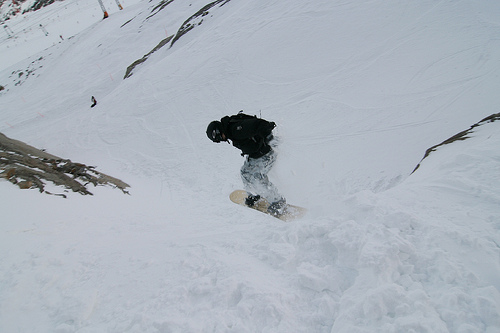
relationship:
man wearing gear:
[205, 109, 289, 218] [239, 120, 271, 159]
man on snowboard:
[205, 109, 289, 218] [228, 189, 305, 224]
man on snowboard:
[205, 109, 289, 218] [230, 182, 295, 215]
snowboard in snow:
[222, 181, 307, 228] [3, 1, 498, 332]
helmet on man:
[205, 119, 222, 144] [205, 109, 289, 218]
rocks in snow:
[3, 129, 131, 201] [3, 1, 498, 332]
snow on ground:
[3, 1, 498, 332] [0, 1, 498, 332]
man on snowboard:
[206, 113, 283, 211] [226, 189, 298, 224]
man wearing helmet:
[204, 110, 289, 216] [203, 120, 229, 145]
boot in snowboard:
[244, 194, 259, 211] [228, 186, 312, 220]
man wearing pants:
[204, 110, 289, 216] [240, 152, 285, 208]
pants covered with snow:
[240, 152, 285, 208] [3, 1, 498, 332]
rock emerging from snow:
[407, 109, 497, 176] [3, 1, 498, 332]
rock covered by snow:
[126, 4, 231, 79] [3, 1, 498, 332]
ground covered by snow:
[0, 1, 498, 332] [3, 1, 498, 332]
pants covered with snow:
[240, 150, 285, 205] [238, 134, 285, 207]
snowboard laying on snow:
[228, 189, 309, 224] [321, 16, 398, 188]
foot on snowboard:
[244, 190, 261, 206] [226, 189, 303, 221]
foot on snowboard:
[263, 197, 289, 214] [226, 189, 303, 221]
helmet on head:
[205, 119, 222, 144] [204, 116, 227, 144]